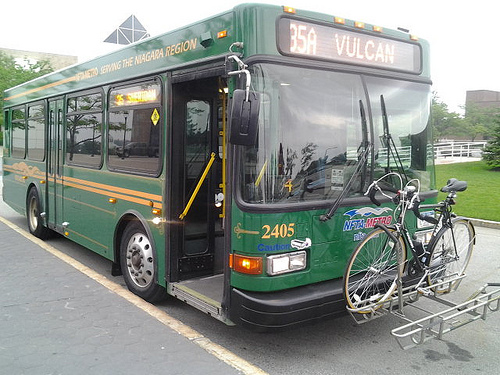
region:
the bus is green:
[3, 3, 479, 285]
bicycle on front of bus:
[338, 127, 494, 340]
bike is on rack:
[333, 160, 491, 326]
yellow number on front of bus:
[243, 198, 306, 248]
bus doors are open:
[151, 57, 263, 313]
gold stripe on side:
[3, 156, 185, 226]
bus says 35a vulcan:
[271, 10, 431, 80]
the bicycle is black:
[322, 141, 493, 293]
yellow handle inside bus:
[162, 130, 244, 229]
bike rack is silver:
[338, 253, 495, 338]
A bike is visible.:
[360, 132, 490, 312]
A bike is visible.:
[340, 207, 440, 347]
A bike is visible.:
[321, 222, 389, 309]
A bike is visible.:
[382, 228, 454, 333]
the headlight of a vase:
[265, 244, 312, 279]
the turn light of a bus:
[222, 251, 269, 283]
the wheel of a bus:
[109, 218, 174, 298]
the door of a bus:
[157, 60, 231, 302]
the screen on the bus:
[263, 8, 428, 78]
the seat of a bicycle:
[441, 173, 469, 197]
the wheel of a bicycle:
[337, 220, 413, 319]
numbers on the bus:
[255, 218, 300, 243]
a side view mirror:
[220, 79, 269, 149]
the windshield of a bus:
[224, 51, 443, 217]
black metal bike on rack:
[340, 168, 487, 315]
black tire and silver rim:
[115, 206, 165, 304]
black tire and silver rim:
[24, 184, 47, 239]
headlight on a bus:
[262, 247, 312, 279]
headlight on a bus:
[412, 226, 436, 248]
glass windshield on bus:
[232, 58, 445, 213]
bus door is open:
[152, 63, 244, 323]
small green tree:
[479, 113, 499, 175]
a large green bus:
[0, 2, 499, 350]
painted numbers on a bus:
[254, 218, 298, 245]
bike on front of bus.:
[336, 168, 479, 310]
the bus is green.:
[1, 1, 438, 328]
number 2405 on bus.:
[255, 216, 297, 244]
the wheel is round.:
[337, 220, 409, 313]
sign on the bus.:
[277, 9, 420, 75]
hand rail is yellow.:
[178, 146, 218, 222]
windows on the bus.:
[4, 73, 168, 179]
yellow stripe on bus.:
[2, 158, 161, 216]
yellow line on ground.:
[1, 210, 270, 373]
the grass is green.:
[423, 147, 498, 225]